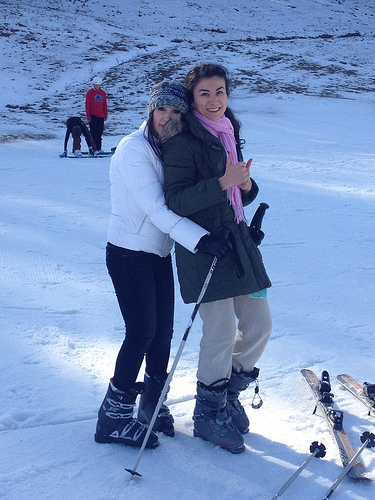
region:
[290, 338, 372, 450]
skis on the snow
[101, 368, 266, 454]
women wearing boots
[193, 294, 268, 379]
woman wearing beige pants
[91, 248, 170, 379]
woman wearing black pants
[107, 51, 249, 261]
woman nestling her head on another woman's shoulder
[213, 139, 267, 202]
woman has both of her thumbs up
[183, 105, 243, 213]
woman wearing a pink scarf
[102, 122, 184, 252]
woman wearing a white jacket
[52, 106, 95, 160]
person bending over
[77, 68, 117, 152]
person wearing a red shirt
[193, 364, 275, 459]
Woman is wearing ski boots.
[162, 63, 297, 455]
Woman is standing on the snow.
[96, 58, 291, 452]
Woman is leaning on other woman.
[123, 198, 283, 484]
Woman is holding ski poles.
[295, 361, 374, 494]
Skis are lying in snow.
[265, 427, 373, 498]
Ski poles are lying in snow.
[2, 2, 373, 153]
Ground can be seen through snow.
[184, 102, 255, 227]
Woman is wearing a pink scarf.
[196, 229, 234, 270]
Woman is wearing black gloves.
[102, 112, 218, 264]
Woman is wearing white jacket.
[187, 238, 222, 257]
Black glove on girl's hand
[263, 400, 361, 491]
Two ski poles on ground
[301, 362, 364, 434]
Two ski's on ground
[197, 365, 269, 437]
Woman wearing gray ski boots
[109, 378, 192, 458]
Woman wearing black ski boots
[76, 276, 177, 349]
Woman wearing black pants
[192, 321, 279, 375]
Woman wearing light colored pants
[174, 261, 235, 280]
Woman wearing black jacket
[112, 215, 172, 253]
Woman wearing white jacket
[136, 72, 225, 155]
Snow hat on girl's head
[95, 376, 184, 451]
a dark colored pair of ski boots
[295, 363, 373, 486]
a pair of skis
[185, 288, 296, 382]
The girl has on grey ski pants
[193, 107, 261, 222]
The girl has on a pink scarfe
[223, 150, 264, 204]
the girl is giving a double thumbs up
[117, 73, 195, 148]
The girl is wearing a hat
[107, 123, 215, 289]
the girl is wearing a white jacket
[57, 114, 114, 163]
the boy is checking his snowboard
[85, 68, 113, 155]
The other boy is wearing a red jacket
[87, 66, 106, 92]
The boy is wearing a helmet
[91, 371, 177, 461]
Black ski boots on girl's feet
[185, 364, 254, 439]
Gray boots on girl's feet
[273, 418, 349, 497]
Two poles on ground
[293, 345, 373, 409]
Two skis on ground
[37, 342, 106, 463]
Ground is covered in snow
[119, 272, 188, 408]
Ski pole in girl's hand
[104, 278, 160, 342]
Girl wearing black pants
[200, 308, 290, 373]
Girl wearing light pants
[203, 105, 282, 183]
Pink scarf on girl's neck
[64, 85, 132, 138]
Person wearing red shirt